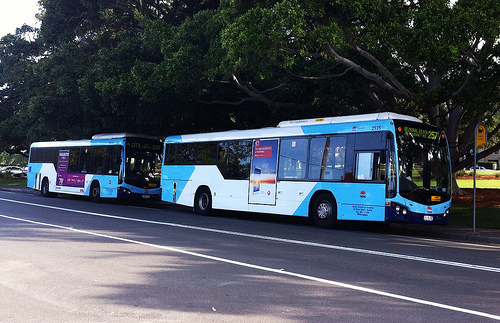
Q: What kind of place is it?
A: It is a pavement.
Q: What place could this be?
A: It is a pavement.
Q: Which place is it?
A: It is a pavement.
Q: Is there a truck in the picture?
A: No, there are no trucks.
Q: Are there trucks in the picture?
A: No, there are no trucks.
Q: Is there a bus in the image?
A: Yes, there is a bus.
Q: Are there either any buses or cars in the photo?
A: Yes, there is a bus.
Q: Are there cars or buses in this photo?
A: Yes, there is a bus.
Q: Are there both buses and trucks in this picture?
A: No, there is a bus but no trucks.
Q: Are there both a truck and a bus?
A: No, there is a bus but no trucks.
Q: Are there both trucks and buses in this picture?
A: No, there is a bus but no trucks.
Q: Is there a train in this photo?
A: No, there are no trains.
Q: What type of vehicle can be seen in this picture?
A: The vehicle is a bus.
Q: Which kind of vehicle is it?
A: The vehicle is a bus.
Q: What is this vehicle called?
A: This is a bus.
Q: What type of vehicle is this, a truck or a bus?
A: This is a bus.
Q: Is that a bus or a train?
A: That is a bus.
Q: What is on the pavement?
A: The bus is on the pavement.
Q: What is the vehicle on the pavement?
A: The vehicle is a bus.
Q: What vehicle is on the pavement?
A: The vehicle is a bus.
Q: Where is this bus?
A: The bus is on the pavement.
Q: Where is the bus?
A: The bus is on the pavement.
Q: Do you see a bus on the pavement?
A: Yes, there is a bus on the pavement.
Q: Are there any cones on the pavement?
A: No, there is a bus on the pavement.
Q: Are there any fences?
A: No, there are no fences.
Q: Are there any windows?
A: Yes, there is a window.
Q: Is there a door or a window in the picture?
A: Yes, there is a window.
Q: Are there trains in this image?
A: No, there are no trains.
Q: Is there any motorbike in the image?
A: No, there are no motorcycles.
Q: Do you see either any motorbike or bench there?
A: No, there are no motorcycles or benches.